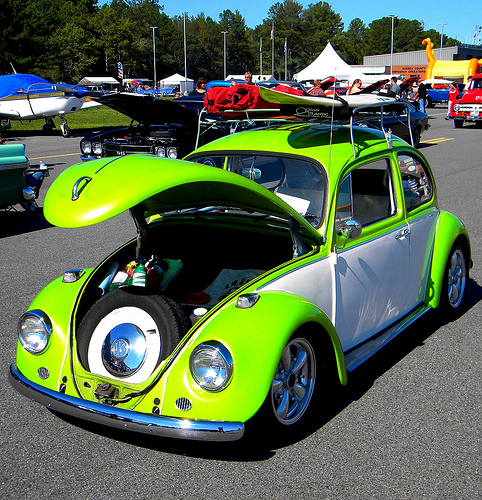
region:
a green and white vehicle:
[45, 119, 449, 419]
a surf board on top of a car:
[246, 68, 410, 158]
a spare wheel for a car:
[43, 283, 183, 401]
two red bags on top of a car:
[202, 81, 279, 145]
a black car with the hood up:
[69, 86, 187, 163]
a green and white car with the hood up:
[16, 137, 331, 430]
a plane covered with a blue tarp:
[8, 57, 76, 128]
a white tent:
[291, 27, 365, 93]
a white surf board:
[243, 84, 400, 117]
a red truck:
[447, 72, 479, 143]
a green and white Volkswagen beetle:
[3, 118, 474, 447]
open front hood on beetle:
[39, 151, 324, 399]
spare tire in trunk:
[76, 285, 192, 386]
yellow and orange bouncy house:
[420, 36, 480, 86]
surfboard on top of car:
[254, 83, 397, 108]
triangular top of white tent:
[289, 40, 370, 82]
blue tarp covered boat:
[0, 61, 86, 139]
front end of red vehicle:
[449, 70, 480, 127]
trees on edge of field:
[0, 0, 461, 82]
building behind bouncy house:
[362, 44, 480, 67]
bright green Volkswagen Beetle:
[9, 102, 475, 453]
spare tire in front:
[74, 281, 181, 389]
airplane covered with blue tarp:
[3, 71, 93, 139]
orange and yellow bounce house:
[417, 38, 478, 87]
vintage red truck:
[445, 74, 481, 136]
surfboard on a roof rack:
[253, 76, 427, 145]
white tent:
[283, 39, 368, 77]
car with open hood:
[64, 78, 230, 157]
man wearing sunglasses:
[239, 70, 254, 87]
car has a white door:
[333, 213, 434, 367]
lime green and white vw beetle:
[17, 97, 460, 428]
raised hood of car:
[43, 137, 295, 266]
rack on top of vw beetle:
[189, 60, 423, 139]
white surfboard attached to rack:
[261, 81, 395, 118]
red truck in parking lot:
[443, 71, 481, 126]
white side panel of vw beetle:
[271, 209, 453, 353]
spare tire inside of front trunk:
[80, 283, 172, 377]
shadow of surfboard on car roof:
[293, 119, 361, 158]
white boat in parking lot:
[7, 75, 92, 126]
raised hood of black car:
[79, 91, 188, 121]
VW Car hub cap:
[95, 317, 155, 387]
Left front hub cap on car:
[174, 336, 250, 410]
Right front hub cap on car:
[14, 296, 58, 368]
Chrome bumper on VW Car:
[2, 349, 291, 456]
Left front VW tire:
[250, 297, 341, 481]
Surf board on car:
[250, 60, 432, 128]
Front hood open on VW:
[38, 130, 335, 298]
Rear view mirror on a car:
[242, 156, 266, 189]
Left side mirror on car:
[331, 213, 375, 252]